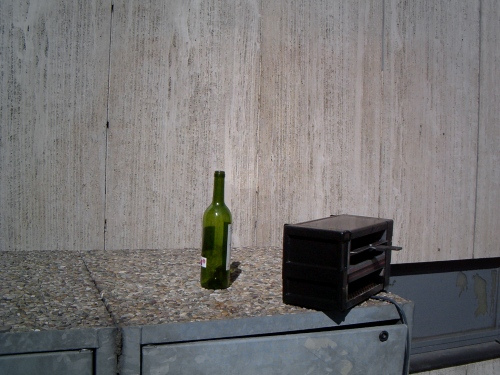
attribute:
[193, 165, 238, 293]
bottle — green, empty, tall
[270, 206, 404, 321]
black object — box, unknown, here, toaster oven, empty, broken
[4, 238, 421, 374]
counter — old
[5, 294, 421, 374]
cabinet — blue, gray, old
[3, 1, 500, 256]
wall — wood, gray, wooden, tan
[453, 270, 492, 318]
paint — chipping, worn off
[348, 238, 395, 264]
tray — removable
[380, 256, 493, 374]
divider — blue